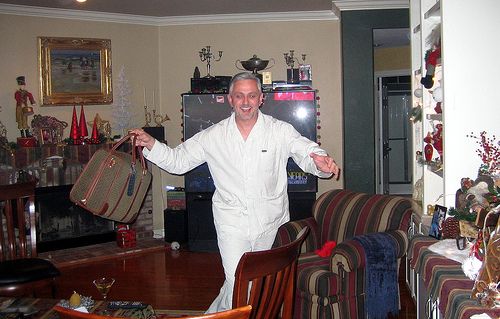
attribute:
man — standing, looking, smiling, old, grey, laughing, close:
[211, 62, 309, 258]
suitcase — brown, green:
[75, 142, 159, 236]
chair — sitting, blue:
[302, 191, 405, 308]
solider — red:
[9, 76, 42, 138]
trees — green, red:
[63, 106, 108, 146]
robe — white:
[206, 132, 293, 219]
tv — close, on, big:
[283, 90, 326, 141]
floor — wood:
[57, 256, 209, 297]